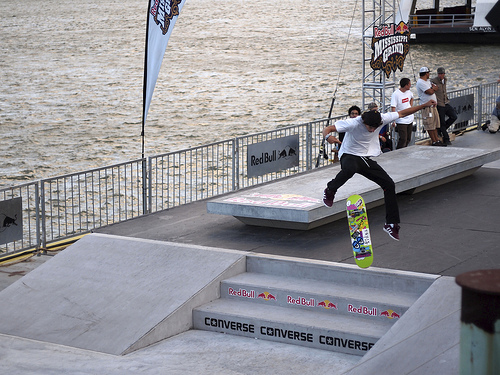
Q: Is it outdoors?
A: Yes, it is outdoors.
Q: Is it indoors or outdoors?
A: It is outdoors.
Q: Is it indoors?
A: No, it is outdoors.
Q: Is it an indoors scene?
A: No, it is outdoors.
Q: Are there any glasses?
A: No, there are no glasses.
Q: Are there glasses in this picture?
A: No, there are no glasses.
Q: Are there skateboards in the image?
A: Yes, there is a skateboard.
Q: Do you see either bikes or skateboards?
A: Yes, there is a skateboard.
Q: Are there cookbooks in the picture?
A: No, there are no cookbooks.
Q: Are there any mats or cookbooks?
A: No, there are no cookbooks or mats.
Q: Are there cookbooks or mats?
A: No, there are no cookbooks or mats.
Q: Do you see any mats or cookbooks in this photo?
A: No, there are no cookbooks or mats.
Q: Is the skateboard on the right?
A: Yes, the skateboard is on the right of the image.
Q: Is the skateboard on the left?
A: No, the skateboard is on the right of the image.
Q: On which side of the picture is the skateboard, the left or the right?
A: The skateboard is on the right of the image.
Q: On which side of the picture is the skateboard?
A: The skateboard is on the right of the image.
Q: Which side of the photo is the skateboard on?
A: The skateboard is on the right of the image.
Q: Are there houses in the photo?
A: No, there are no houses.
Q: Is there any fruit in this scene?
A: Yes, there is a fruit.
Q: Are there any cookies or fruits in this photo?
A: Yes, there is a fruit.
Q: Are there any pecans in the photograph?
A: No, there are no pecans.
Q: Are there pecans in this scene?
A: No, there are no pecans.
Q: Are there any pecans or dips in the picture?
A: No, there are no pecans or dips.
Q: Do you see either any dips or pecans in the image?
A: No, there are no pecans or dips.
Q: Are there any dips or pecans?
A: No, there are no pecans or dips.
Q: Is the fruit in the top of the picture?
A: Yes, the fruit is in the top of the image.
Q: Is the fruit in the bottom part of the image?
A: No, the fruit is in the top of the image.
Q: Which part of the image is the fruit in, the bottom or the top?
A: The fruit is in the top of the image.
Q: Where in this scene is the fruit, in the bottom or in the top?
A: The fruit is in the top of the image.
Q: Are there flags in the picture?
A: Yes, there is a flag.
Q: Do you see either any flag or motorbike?
A: Yes, there is a flag.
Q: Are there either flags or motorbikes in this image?
A: Yes, there is a flag.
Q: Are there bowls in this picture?
A: No, there are no bowls.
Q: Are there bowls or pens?
A: No, there are no bowls or pens.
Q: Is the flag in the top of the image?
A: Yes, the flag is in the top of the image.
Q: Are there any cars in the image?
A: No, there are no cars.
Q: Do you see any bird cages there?
A: No, there are no bird cages.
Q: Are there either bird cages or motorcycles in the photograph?
A: No, there are no bird cages or motorcycles.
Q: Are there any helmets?
A: No, there are no helmets.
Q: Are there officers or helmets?
A: No, there are no helmets or officers.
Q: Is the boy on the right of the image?
A: Yes, the boy is on the right of the image.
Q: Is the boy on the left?
A: No, the boy is on the right of the image.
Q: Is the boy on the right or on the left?
A: The boy is on the right of the image.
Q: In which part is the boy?
A: The boy is on the right of the image.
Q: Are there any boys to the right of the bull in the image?
A: Yes, there is a boy to the right of the bull.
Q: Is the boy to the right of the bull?
A: Yes, the boy is to the right of the bull.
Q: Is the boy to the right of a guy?
A: No, the boy is to the right of the bull.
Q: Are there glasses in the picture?
A: No, there are no glasses.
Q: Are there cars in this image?
A: No, there are no cars.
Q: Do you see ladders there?
A: No, there are no ladders.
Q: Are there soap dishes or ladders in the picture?
A: No, there are no ladders or soap dishes.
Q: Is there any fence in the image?
A: Yes, there is a fence.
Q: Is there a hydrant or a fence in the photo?
A: Yes, there is a fence.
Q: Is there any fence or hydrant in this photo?
A: Yes, there is a fence.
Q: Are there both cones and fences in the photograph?
A: No, there is a fence but no cones.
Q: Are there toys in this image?
A: No, there are no toys.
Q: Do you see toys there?
A: No, there are no toys.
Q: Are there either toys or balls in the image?
A: No, there are no toys or balls.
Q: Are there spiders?
A: No, there are no spiders.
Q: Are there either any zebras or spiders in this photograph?
A: No, there are no spiders or zebras.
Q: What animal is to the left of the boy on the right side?
A: The animal is a bull.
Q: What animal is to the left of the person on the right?
A: The animal is a bull.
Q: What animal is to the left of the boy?
A: The animal is a bull.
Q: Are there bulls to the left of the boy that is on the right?
A: Yes, there is a bull to the left of the boy.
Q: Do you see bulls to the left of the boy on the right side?
A: Yes, there is a bull to the left of the boy.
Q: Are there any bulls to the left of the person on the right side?
A: Yes, there is a bull to the left of the boy.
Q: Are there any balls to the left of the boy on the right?
A: No, there is a bull to the left of the boy.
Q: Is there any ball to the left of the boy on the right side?
A: No, there is a bull to the left of the boy.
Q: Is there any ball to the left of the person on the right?
A: No, there is a bull to the left of the boy.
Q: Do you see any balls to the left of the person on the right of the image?
A: No, there is a bull to the left of the boy.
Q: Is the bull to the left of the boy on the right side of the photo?
A: Yes, the bull is to the left of the boy.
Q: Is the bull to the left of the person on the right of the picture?
A: Yes, the bull is to the left of the boy.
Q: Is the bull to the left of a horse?
A: No, the bull is to the left of the boy.